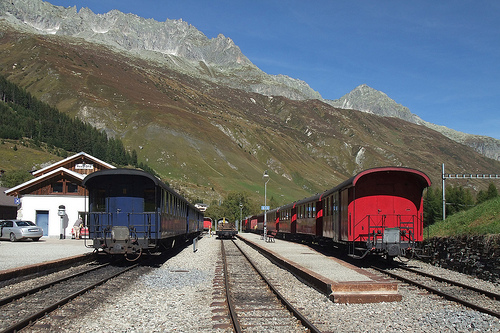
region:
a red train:
[241, 163, 431, 264]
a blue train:
[81, 166, 201, 263]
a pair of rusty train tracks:
[208, 235, 323, 332]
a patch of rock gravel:
[129, 270, 209, 331]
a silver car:
[0, 218, 42, 242]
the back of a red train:
[348, 166, 430, 265]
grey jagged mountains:
[0, 1, 499, 150]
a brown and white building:
[8, 148, 114, 241]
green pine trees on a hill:
[0, 71, 126, 153]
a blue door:
[34, 208, 50, 233]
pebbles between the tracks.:
[157, 280, 190, 317]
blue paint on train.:
[115, 199, 138, 210]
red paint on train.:
[357, 199, 390, 207]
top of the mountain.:
[357, 82, 375, 97]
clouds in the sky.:
[320, 63, 340, 83]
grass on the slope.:
[466, 205, 493, 229]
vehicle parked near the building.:
[12, 220, 39, 239]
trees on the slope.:
[51, 113, 79, 136]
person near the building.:
[72, 216, 84, 238]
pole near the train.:
[261, 169, 273, 236]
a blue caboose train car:
[79, 168, 189, 262]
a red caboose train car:
[320, 168, 429, 264]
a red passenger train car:
[294, 192, 322, 243]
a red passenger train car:
[278, 199, 295, 238]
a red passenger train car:
[259, 204, 276, 233]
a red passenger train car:
[245, 211, 257, 228]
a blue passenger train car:
[184, 198, 200, 238]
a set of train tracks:
[215, 229, 318, 331]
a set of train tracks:
[373, 253, 498, 320]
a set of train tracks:
[0, 250, 141, 331]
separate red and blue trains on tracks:
[78, 157, 428, 272]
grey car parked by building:
[0, 166, 80, 241]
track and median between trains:
[182, 192, 392, 322]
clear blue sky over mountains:
[57, 0, 497, 145]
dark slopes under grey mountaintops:
[6, 0, 481, 262]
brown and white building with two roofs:
[5, 145, 111, 240]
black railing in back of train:
[80, 205, 155, 260]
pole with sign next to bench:
[255, 165, 275, 245]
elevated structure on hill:
[430, 150, 495, 222]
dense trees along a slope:
[3, 67, 158, 189]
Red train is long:
[246, 191, 423, 248]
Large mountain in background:
[7, 4, 482, 201]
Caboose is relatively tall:
[314, 170, 425, 250]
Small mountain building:
[26, 144, 118, 241]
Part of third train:
[214, 208, 238, 245]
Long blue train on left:
[87, 144, 211, 257]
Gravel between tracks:
[144, 263, 222, 320]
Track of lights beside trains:
[433, 156, 498, 216]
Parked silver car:
[2, 210, 43, 246]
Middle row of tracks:
[214, 233, 311, 330]